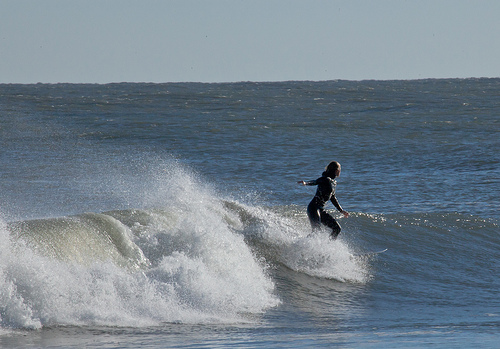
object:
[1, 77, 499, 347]
ocean water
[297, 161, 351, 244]
woman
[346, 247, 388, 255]
surfboard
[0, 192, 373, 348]
crashing waves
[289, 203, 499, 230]
ripples